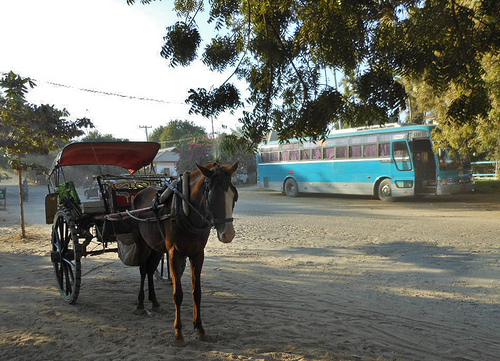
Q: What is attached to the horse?
A: A buggy.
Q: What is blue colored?
A: A bus.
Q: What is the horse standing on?
A: Sand.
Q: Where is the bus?
A: In the back by the house.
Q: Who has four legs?
A: The horse.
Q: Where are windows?
A: On the bus.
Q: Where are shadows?
A: On the dirt.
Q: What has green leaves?
A: The trees.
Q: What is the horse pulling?
A: A carriage.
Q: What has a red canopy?
A: The carriage.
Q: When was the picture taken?
A: During the daytime.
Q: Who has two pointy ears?
A: A horse.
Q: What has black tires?
A: The bus.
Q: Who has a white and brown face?
A: Horse.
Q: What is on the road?
A: Dirt road with tire tracks.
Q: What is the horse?
A: Brown and white horse.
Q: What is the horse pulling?
A: Horse is pulling a carriage.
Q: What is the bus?
A: The bus is blue and silver.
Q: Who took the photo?
A: A photographer.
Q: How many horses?
A: One.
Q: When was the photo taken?
A: Daytime.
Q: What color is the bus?
A: Aqua.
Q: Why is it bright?
A: Sunny.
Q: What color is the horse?
A: Brown.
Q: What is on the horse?
A: A carrige.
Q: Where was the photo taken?
A: On a dirt road.